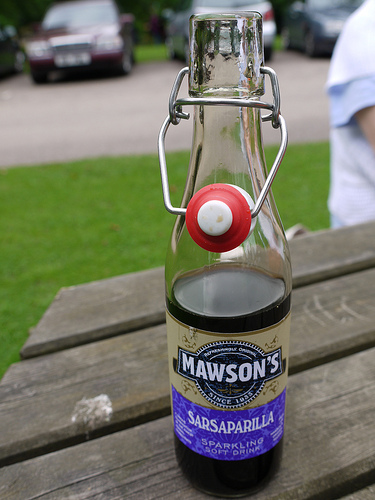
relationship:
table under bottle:
[1, 221, 373, 499] [158, 6, 304, 492]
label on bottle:
[173, 340, 286, 409] [158, 6, 304, 492]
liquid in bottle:
[164, 261, 292, 491] [158, 6, 304, 492]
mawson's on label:
[180, 352, 279, 381] [177, 350, 281, 383]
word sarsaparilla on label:
[187, 409, 275, 430] [166, 314, 289, 460]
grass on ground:
[2, 136, 330, 373] [5, 59, 373, 371]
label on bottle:
[151, 319, 303, 392] [158, 6, 304, 492]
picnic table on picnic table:
[1, 218, 375, 500] [1, 220, 373, 498]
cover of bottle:
[185, 183, 251, 253] [158, 6, 304, 492]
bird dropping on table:
[67, 390, 113, 443] [52, 287, 148, 363]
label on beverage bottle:
[173, 340, 286, 409] [128, 9, 317, 498]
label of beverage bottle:
[173, 340, 286, 409] [157, 10, 292, 498]